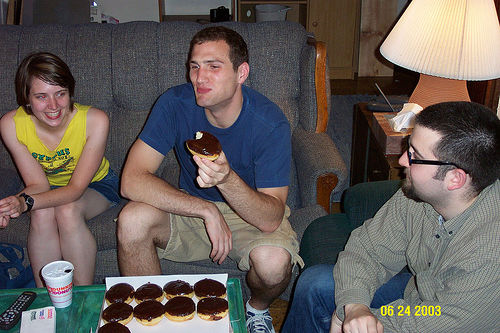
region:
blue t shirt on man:
[151, 73, 298, 210]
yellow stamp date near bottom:
[378, 301, 456, 319]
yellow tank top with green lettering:
[4, 106, 134, 210]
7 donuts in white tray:
[98, 269, 230, 331]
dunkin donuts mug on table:
[41, 262, 78, 301]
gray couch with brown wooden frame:
[123, 8, 379, 184]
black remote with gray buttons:
[9, 290, 34, 331]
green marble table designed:
[82, 277, 86, 332]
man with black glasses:
[387, 142, 466, 182]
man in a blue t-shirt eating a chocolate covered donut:
[115, 25, 305, 331]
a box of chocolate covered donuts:
[94, 272, 229, 332]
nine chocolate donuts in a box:
[97, 278, 226, 332]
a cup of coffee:
[40, 259, 75, 308]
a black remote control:
[0, 289, 37, 330]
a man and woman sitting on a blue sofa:
[0, 20, 349, 302]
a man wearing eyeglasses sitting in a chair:
[279, 100, 499, 331]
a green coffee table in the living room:
[12, 276, 247, 331]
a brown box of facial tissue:
[370, 101, 409, 153]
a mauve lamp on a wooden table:
[377, 0, 499, 99]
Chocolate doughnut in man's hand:
[179, 127, 226, 165]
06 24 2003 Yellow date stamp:
[372, 296, 447, 323]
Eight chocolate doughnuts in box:
[99, 278, 226, 331]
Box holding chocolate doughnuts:
[91, 269, 249, 331]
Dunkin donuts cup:
[35, 257, 81, 310]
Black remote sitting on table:
[0, 287, 39, 331]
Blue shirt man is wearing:
[127, 80, 302, 210]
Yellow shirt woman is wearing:
[8, 95, 115, 189]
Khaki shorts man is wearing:
[146, 187, 309, 274]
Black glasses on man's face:
[392, 130, 469, 180]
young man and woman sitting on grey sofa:
[0, 24, 348, 332]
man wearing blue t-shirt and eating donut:
[112, 24, 303, 330]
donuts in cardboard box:
[93, 275, 231, 332]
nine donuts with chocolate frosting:
[98, 279, 227, 331]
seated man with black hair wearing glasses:
[276, 102, 498, 332]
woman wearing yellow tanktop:
[0, 49, 120, 286]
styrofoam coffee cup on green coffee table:
[40, 259, 77, 309]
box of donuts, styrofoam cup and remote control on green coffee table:
[0, 259, 250, 331]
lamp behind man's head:
[378, 0, 498, 104]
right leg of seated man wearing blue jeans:
[281, 261, 410, 332]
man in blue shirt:
[160, 91, 295, 190]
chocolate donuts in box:
[112, 293, 187, 330]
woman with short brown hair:
[19, 49, 76, 116]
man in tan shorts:
[182, 205, 308, 253]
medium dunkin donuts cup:
[46, 265, 76, 310]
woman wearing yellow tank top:
[17, 123, 111, 205]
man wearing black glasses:
[401, 138, 466, 182]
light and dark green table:
[77, 299, 102, 314]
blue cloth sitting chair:
[327, 221, 386, 241]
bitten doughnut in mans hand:
[184, 126, 232, 196]